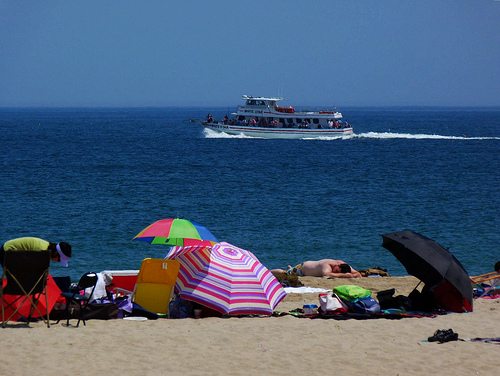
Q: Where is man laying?
A: Beach.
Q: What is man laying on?
A: Sand.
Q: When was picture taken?
A: Day time.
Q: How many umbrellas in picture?
A: Three.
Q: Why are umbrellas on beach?
A: Provide shade.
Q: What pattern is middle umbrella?
A: Stripes.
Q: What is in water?
A: Boat.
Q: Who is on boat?
A: Passengers.